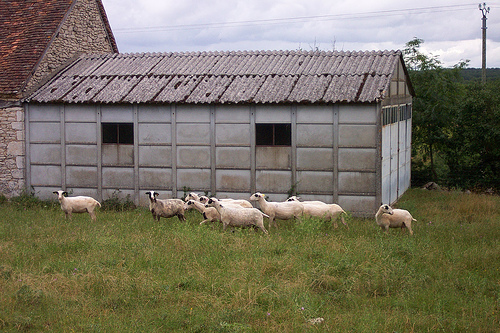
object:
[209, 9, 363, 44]
clouds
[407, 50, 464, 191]
tree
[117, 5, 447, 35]
utilty lines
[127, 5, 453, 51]
sky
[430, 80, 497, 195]
bushes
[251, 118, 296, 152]
window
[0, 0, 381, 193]
house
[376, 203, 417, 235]
animal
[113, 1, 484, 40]
wires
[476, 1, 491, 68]
pole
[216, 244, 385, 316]
vase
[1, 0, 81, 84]
roof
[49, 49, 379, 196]
building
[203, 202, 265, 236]
goats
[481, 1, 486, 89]
utility pole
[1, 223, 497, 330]
field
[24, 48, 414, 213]
shed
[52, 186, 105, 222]
goats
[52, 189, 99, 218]
animals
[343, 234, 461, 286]
grass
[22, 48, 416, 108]
roof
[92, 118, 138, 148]
openings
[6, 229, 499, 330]
ground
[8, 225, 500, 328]
land